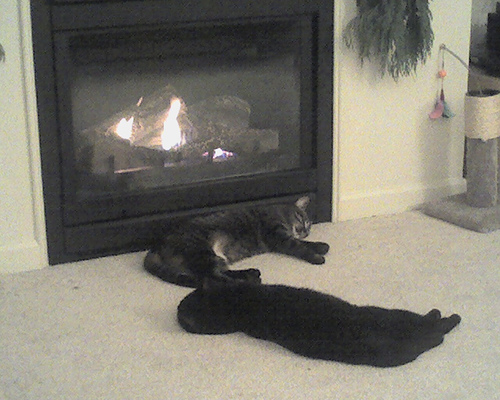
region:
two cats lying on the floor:
[119, 199, 456, 362]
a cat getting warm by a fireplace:
[143, 195, 330, 281]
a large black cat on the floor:
[166, 267, 450, 362]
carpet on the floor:
[16, 289, 179, 389]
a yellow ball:
[435, 65, 451, 77]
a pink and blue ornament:
[434, 90, 456, 123]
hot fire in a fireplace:
[111, 107, 197, 151]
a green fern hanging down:
[349, 0, 439, 73]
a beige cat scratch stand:
[431, 95, 498, 229]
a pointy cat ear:
[297, 195, 315, 209]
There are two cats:
[140, 189, 464, 366]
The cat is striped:
[141, 192, 328, 286]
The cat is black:
[177, 259, 460, 369]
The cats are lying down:
[144, 194, 461, 367]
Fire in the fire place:
[61, 25, 308, 197]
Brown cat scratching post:
[422, 40, 495, 232]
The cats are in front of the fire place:
[35, 8, 465, 372]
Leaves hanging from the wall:
[341, 2, 433, 77]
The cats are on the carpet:
[137, 196, 467, 366]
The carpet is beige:
[8, 189, 492, 397]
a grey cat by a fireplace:
[141, 190, 330, 287]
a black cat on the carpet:
[170, 272, 464, 372]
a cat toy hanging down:
[427, 42, 456, 121]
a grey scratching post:
[422, 86, 498, 237]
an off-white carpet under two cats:
[0, 211, 498, 399]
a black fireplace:
[42, 0, 338, 260]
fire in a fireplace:
[161, 94, 186, 150]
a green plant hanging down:
[342, 0, 434, 81]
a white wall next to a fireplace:
[336, 1, 474, 227]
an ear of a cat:
[294, 193, 314, 210]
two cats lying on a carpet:
[134, 178, 471, 365]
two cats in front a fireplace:
[20, 0, 467, 378]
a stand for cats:
[428, 39, 498, 229]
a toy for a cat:
[423, 38, 499, 145]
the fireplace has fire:
[33, 0, 329, 252]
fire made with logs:
[96, 82, 275, 165]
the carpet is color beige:
[5, 202, 499, 395]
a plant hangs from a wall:
[343, 0, 439, 85]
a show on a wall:
[410, 105, 461, 211]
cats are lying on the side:
[134, 182, 476, 379]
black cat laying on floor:
[197, 277, 402, 377]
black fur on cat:
[237, 289, 338, 351]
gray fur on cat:
[223, 223, 295, 258]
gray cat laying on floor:
[191, 215, 324, 243]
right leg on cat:
[282, 225, 334, 266]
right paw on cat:
[311, 251, 326, 265]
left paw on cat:
[314, 237, 333, 257]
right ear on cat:
[291, 188, 313, 210]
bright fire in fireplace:
[114, 88, 234, 153]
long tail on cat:
[145, 255, 227, 315]